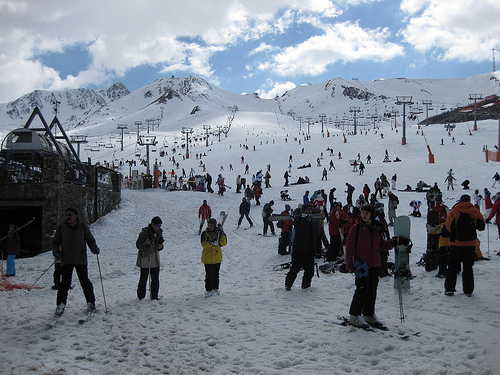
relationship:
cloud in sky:
[400, 0, 498, 64] [1, 0, 496, 107]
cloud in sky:
[2, 2, 244, 47] [22, 1, 499, 89]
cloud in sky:
[87, 39, 228, 83] [22, 1, 499, 89]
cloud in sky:
[255, 18, 405, 78] [22, 1, 499, 89]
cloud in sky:
[395, 0, 499, 64] [22, 1, 499, 89]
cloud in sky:
[0, 56, 64, 107] [22, 1, 499, 89]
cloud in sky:
[255, 18, 405, 78] [253, 1, 498, 87]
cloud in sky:
[400, 0, 498, 64] [380, 29, 420, 70]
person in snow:
[135, 216, 164, 302] [0, 80, 496, 371]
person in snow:
[54, 207, 100, 315] [0, 80, 496, 371]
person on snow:
[344, 204, 400, 329] [0, 80, 496, 371]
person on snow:
[438, 193, 485, 297] [0, 80, 496, 371]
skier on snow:
[283, 199, 330, 293] [0, 80, 496, 371]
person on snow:
[200, 219, 228, 298] [0, 80, 496, 371]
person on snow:
[135, 216, 164, 302] [0, 80, 496, 371]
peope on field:
[261, 146, 499, 334] [5, 122, 497, 372]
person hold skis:
[200, 219, 228, 298] [386, 207, 421, 359]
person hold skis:
[135, 216, 164, 302] [386, 207, 421, 359]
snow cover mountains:
[45, 80, 484, 117] [2, 62, 498, 141]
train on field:
[5, 120, 124, 263] [2, 173, 498, 366]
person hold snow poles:
[344, 194, 386, 330] [391, 235, 408, 329]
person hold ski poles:
[48, 206, 99, 310] [27, 253, 109, 314]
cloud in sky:
[255, 18, 405, 78] [4, 4, 498, 85]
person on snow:
[54, 207, 100, 315] [20, 197, 492, 373]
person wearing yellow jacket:
[195, 213, 227, 298] [198, 225, 228, 266]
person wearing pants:
[344, 204, 400, 329] [344, 250, 384, 324]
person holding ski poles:
[54, 207, 100, 315] [29, 253, 110, 307]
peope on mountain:
[255, 125, 465, 297] [2, 64, 484, 134]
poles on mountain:
[113, 99, 233, 163] [55, 60, 255, 175]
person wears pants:
[0, 222, 18, 278] [5, 254, 15, 276]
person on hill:
[135, 216, 164, 302] [44, 82, 496, 204]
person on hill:
[54, 207, 100, 315] [15, 172, 497, 362]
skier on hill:
[285, 203, 331, 290] [4, 150, 493, 373]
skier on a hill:
[363, 152, 373, 166] [350, 134, 378, 153]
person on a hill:
[344, 204, 400, 329] [160, 189, 194, 220]